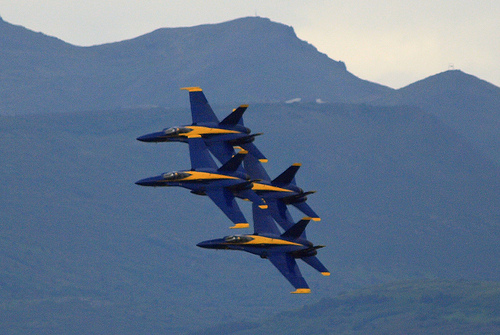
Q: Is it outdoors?
A: Yes, it is outdoors.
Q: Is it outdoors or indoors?
A: It is outdoors.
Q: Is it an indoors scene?
A: No, it is outdoors.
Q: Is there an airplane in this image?
A: Yes, there are airplanes.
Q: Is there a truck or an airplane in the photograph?
A: Yes, there are airplanes.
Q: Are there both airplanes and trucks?
A: No, there are airplanes but no trucks.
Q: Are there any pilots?
A: No, there are no pilots.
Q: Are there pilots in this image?
A: No, there are no pilots.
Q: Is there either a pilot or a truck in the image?
A: No, there are no pilots or trucks.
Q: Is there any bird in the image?
A: No, there are no birds.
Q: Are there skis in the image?
A: No, there are no skis.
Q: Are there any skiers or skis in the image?
A: No, there are no skis or skiers.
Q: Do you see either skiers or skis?
A: No, there are no skis or skiers.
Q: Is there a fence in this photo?
A: No, there are no fences.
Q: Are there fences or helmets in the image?
A: No, there are no fences or helmets.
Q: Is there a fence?
A: No, there are no fences.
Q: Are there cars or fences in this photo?
A: No, there are no fences or cars.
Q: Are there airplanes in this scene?
A: Yes, there is an airplane.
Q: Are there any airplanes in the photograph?
A: Yes, there is an airplane.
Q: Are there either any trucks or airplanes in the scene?
A: Yes, there is an airplane.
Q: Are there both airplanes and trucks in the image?
A: No, there is an airplane but no trucks.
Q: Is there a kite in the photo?
A: No, there are no kites.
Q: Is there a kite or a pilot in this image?
A: No, there are no kites or pilots.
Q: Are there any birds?
A: No, there are no birds.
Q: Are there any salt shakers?
A: No, there are no salt shakers.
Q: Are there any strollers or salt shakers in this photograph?
A: No, there are no salt shakers or strollers.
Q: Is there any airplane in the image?
A: Yes, there are airplanes.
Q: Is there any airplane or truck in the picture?
A: Yes, there are airplanes.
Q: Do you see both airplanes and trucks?
A: No, there are airplanes but no trucks.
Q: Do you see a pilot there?
A: No, there are no pilots.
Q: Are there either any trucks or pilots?
A: No, there are no pilots or trucks.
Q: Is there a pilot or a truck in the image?
A: No, there are no pilots or trucks.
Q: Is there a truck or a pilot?
A: No, there are no pilots or trucks.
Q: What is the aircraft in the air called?
A: The aircraft is airplanes.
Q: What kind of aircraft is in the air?
A: The aircraft is airplanes.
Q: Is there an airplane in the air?
A: Yes, there are airplanes in the air.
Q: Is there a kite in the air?
A: No, there are airplanes in the air.